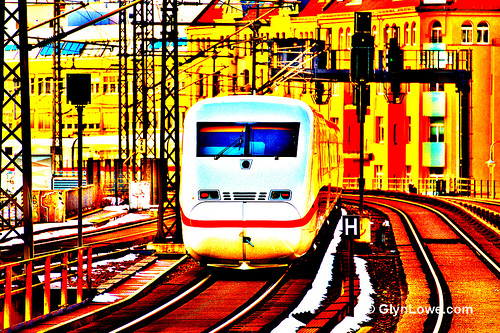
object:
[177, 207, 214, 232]
line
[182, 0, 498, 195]
building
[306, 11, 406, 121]
lights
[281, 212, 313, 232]
red line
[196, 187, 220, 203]
light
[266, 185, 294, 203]
light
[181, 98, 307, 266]
front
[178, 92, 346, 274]
train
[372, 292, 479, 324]
credit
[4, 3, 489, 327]
image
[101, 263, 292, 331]
rails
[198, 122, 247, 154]
window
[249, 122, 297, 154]
window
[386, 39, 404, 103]
traffic light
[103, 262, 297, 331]
track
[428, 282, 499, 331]
track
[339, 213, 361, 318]
sign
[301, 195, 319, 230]
stripe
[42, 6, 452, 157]
bad sentence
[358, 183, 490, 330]
track